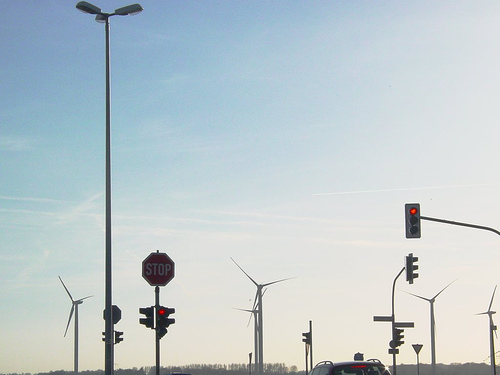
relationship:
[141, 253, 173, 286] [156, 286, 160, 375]
sign on pole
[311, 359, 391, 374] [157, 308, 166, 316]
car at light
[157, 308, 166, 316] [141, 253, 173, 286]
light by sign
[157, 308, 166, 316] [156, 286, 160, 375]
light attached to pole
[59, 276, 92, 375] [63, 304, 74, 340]
wind mill has propeller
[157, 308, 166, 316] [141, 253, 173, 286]
light next to sign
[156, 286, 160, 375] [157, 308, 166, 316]
pole holding up light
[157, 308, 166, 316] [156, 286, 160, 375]
light on pole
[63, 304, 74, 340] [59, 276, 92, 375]
propeller on wind mill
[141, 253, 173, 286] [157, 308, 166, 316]
sign above light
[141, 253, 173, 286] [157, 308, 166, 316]
sign on top of light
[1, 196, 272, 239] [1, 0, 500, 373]
trail in sky